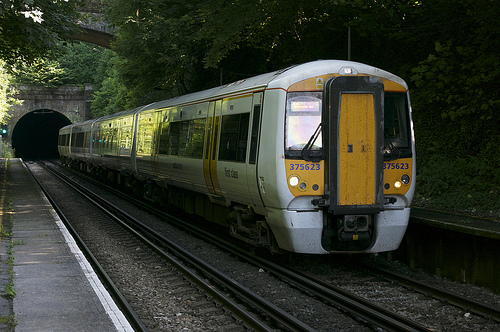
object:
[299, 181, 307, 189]
light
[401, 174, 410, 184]
light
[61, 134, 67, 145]
window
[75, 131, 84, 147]
window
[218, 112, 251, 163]
window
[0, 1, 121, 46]
railing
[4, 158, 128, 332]
path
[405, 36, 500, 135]
tree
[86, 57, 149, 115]
tree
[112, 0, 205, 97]
tree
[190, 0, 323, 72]
tree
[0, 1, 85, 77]
tree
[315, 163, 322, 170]
number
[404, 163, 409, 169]
number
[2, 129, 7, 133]
light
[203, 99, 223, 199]
door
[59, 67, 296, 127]
white roof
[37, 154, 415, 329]
railway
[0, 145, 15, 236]
grass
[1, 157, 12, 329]
concrete cracks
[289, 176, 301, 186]
headlight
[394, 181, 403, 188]
headlight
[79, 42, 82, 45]
leaf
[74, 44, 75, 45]
leaf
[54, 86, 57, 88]
leaf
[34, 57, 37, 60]
leaf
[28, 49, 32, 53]
leaf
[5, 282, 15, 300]
grass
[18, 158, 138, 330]
lines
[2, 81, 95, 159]
tunnel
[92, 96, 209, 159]
reflection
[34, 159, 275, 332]
rails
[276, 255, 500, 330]
tracks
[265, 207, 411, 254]
bumper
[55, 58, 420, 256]
train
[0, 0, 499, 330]
picture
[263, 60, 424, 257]
front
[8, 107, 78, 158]
entrance